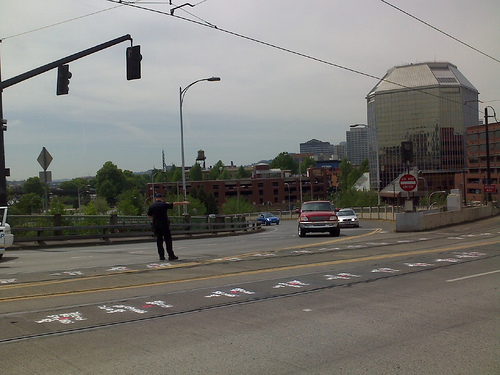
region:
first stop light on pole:
[121, 45, 145, 84]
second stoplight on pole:
[48, 62, 79, 98]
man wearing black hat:
[153, 193, 165, 198]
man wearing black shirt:
[153, 216, 163, 224]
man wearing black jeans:
[154, 230, 166, 247]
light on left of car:
[296, 216, 313, 223]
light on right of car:
[326, 213, 341, 223]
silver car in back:
[348, 212, 355, 223]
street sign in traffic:
[398, 174, 418, 191]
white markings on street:
[375, 256, 400, 283]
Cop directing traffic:
[140, 180, 187, 265]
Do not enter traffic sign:
[394, 165, 424, 197]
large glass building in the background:
[344, 47, 477, 190]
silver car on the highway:
[336, 203, 359, 226]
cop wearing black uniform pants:
[149, 219, 178, 257]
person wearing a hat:
[145, 189, 167, 202]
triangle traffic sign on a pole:
[31, 144, 58, 171]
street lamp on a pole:
[201, 60, 222, 88]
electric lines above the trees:
[177, 3, 491, 98]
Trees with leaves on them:
[79, 149, 131, 209]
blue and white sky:
[213, 64, 294, 161]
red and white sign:
[392, 169, 417, 199]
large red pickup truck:
[294, 195, 347, 237]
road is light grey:
[291, 288, 396, 345]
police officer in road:
[144, 191, 189, 273]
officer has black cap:
[143, 190, 171, 207]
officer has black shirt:
[137, 191, 167, 218]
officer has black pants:
[153, 219, 166, 262]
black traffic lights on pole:
[45, 24, 142, 123]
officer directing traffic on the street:
[140, 191, 198, 255]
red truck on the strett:
[296, 197, 339, 236]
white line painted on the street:
[443, 268, 497, 295]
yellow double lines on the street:
[6, 227, 491, 309]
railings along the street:
[10, 213, 264, 246]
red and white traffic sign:
[398, 171, 418, 191]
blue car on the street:
[259, 210, 283, 227]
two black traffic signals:
[50, 45, 140, 93]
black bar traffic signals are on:
[2, 26, 133, 92]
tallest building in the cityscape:
[360, 57, 481, 197]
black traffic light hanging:
[120, 36, 147, 76]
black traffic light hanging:
[52, 62, 79, 96]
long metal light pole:
[10, 29, 135, 103]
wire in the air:
[174, 6, 358, 88]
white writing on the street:
[52, 292, 179, 349]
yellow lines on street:
[20, 268, 121, 316]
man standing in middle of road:
[140, 176, 198, 283]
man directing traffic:
[140, 181, 197, 276]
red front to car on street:
[291, 196, 349, 244]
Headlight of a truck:
[295, 213, 310, 224]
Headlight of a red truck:
[301, 212, 314, 227]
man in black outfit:
[136, 183, 186, 265]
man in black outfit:
[136, 180, 192, 270]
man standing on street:
[133, 180, 189, 270]